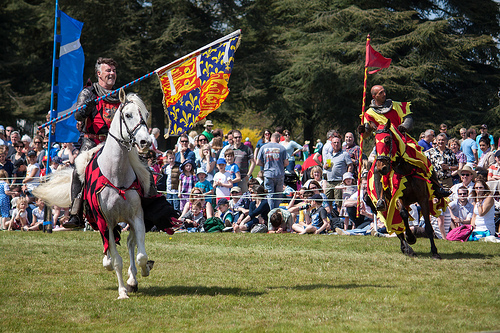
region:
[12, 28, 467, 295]
two men are riding horses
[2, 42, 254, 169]
the man is holding a flag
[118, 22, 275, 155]
the flag is multi colored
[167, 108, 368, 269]
many people are watching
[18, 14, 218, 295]
the horse on the left is white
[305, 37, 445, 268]
the horse on the right is brown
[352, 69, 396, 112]
the man has a bald head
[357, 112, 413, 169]
the horse is wearing a mask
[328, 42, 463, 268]
the horse is in motion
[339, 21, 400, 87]
the flag is red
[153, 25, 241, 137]
A red yellow and blue flag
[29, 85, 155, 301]
A white horse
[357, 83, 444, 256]
The man is riding a horse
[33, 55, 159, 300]
Man riding a white horse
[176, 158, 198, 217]
Little girl wearing a blue hat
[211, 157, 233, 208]
Kid wearing a blue hat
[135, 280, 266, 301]
Shadowing on the grassy ground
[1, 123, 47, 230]
Group of people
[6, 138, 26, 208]
Lady wearing dark sunglasses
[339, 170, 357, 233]
A child wearing a hat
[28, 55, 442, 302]
Two men on horses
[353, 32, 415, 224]
Man holding a red and yellow flag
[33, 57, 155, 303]
Man on a white horse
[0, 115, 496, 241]
Audience of people watching an outdoor show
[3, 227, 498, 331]
Area of grass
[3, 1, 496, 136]
Full tall green trees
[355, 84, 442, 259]
Man on a brown horse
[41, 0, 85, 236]
Tall blue flag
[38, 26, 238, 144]
Man holding a multi-colored flag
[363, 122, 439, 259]
Brown horse wearing red and yellow gear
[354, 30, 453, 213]
rider with colors yellow and red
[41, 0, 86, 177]
blue and gray banner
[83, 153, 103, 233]
black and red diamond pattern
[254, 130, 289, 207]
man wearing T-shirt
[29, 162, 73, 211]
horse-tail in motion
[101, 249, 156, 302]
horse hooves in motion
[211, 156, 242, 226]
three boys wearing hats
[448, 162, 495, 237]
three people wearing sunglasses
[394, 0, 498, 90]
green pine tree branches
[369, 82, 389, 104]
a man's balding head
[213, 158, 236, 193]
person in the crowd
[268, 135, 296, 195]
person in the crowd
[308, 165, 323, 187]
person in the crowd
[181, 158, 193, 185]
person in the crowd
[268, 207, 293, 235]
person in the crowd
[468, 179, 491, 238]
person in the crowd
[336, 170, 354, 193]
person in the crowd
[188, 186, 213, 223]
person in the crowd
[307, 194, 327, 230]
person in the crowd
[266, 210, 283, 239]
person in the crowd